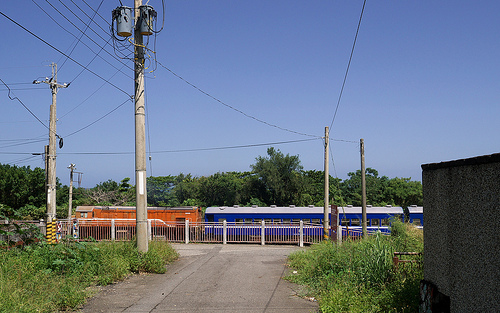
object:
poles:
[44, 212, 56, 247]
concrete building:
[422, 154, 500, 310]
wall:
[5, 207, 77, 245]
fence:
[56, 213, 422, 248]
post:
[297, 217, 306, 247]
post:
[258, 219, 266, 244]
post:
[221, 219, 228, 244]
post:
[181, 219, 191, 244]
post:
[110, 218, 115, 241]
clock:
[235, 178, 253, 207]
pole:
[132, 2, 149, 252]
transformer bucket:
[113, 4, 131, 36]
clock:
[367, 219, 397, 254]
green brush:
[296, 217, 455, 311]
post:
[360, 139, 368, 237]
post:
[324, 126, 330, 230]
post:
[131, 0, 148, 255]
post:
[67, 170, 72, 242]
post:
[46, 85, 56, 225]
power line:
[3, 132, 325, 157]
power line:
[327, 135, 362, 145]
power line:
[328, 0, 370, 136]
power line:
[53, 90, 138, 142]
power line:
[41, 1, 106, 83]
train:
[68, 201, 435, 246]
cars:
[201, 205, 422, 244]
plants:
[1, 225, 180, 310]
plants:
[284, 215, 424, 310]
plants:
[0, 165, 425, 218]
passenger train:
[75, 203, 203, 235]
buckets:
[110, 5, 143, 40]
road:
[84, 237, 315, 313]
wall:
[212, 205, 428, 249]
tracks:
[45, 234, 415, 249]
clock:
[404, 276, 453, 304]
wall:
[420, 154, 500, 302]